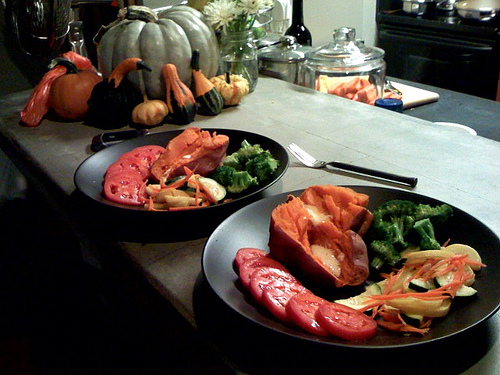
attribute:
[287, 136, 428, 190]
fork —  Metal 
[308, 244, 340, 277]
butter — melted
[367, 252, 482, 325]
carrot slices — skinny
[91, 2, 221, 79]
pumpkin — gray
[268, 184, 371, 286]
sweet potato — baked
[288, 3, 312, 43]
bottle — black, glass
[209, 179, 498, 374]
plate — black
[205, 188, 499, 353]
bowl — black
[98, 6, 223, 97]
pumpkin — ceramic, gray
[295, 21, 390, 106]
glass jar — clear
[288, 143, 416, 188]
fork — metal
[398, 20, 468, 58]
pull handle — black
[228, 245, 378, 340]
tomatoes — red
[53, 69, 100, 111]
pumpkin — orange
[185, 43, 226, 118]
gourd — orange, green